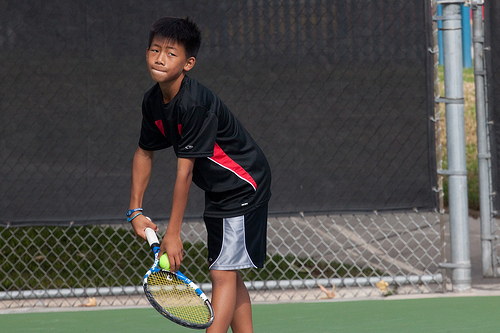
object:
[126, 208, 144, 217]
bracelet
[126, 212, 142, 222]
bracelet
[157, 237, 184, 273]
hand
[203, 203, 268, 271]
shorts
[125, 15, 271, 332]
boy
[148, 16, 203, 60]
hair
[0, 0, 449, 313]
fence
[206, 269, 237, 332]
leg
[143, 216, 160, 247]
handle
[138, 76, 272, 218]
t-shirt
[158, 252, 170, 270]
ball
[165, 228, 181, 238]
wrist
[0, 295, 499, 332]
court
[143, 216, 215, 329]
racquet